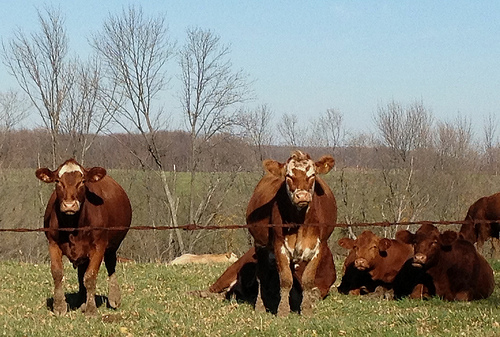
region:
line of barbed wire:
[6, 208, 498, 234]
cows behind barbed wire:
[30, 148, 494, 313]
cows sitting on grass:
[337, 213, 499, 327]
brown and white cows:
[18, 145, 333, 307]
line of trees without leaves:
[13, 21, 498, 261]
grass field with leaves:
[2, 263, 497, 335]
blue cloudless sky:
[4, 5, 497, 155]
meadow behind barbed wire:
[5, 207, 495, 334]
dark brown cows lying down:
[341, 203, 494, 295]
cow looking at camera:
[14, 125, 147, 318]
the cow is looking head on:
[30, 158, 130, 311]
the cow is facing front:
[249, 151, 336, 325]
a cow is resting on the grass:
[340, 225, 416, 297]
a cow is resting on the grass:
[398, 220, 495, 307]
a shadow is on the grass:
[46, 289, 118, 315]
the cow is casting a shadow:
[35, 159, 130, 314]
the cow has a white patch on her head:
[54, 161, 85, 178]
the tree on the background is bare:
[11, 10, 105, 260]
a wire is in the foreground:
[3, 219, 498, 237]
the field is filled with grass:
[1, 165, 498, 331]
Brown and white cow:
[27, 152, 165, 311]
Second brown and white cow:
[237, 141, 351, 326]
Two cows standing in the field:
[24, 142, 336, 314]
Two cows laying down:
[349, 218, 488, 306]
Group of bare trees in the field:
[17, 17, 254, 263]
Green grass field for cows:
[3, 258, 498, 333]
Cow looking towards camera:
[35, 146, 142, 306]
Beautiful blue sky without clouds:
[1, 6, 491, 151]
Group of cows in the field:
[27, 150, 497, 306]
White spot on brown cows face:
[52, 156, 92, 188]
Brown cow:
[32, 158, 132, 311]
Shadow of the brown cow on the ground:
[45, 289, 119, 316]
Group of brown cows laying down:
[340, 219, 495, 303]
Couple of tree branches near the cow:
[0, 7, 258, 264]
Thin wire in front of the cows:
[1, 214, 498, 234]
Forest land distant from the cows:
[4, 126, 499, 165]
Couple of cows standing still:
[32, 152, 337, 316]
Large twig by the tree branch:
[166, 249, 243, 266]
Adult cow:
[241, 148, 339, 312]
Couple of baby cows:
[338, 223, 498, 301]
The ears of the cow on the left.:
[30, 165, 112, 180]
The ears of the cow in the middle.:
[264, 155, 335, 173]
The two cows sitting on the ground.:
[336, 217, 496, 314]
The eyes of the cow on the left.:
[55, 178, 85, 188]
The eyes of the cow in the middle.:
[286, 169, 314, 181]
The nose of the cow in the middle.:
[290, 191, 311, 201]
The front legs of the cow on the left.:
[44, 236, 100, 319]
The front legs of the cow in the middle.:
[281, 242, 317, 317]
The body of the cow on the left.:
[35, 170, 132, 242]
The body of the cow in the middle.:
[245, 162, 331, 239]